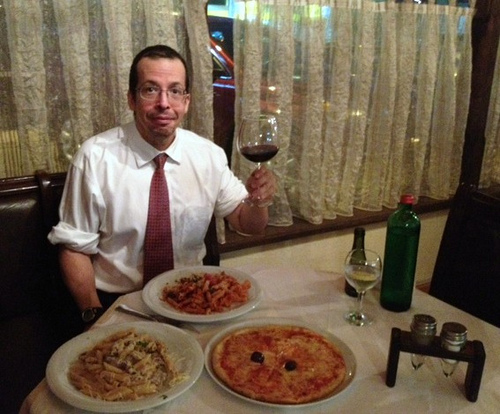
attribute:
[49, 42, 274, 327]
man — smiling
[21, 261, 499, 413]
table — white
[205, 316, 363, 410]
plate — white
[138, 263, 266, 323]
plate — white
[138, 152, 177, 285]
tie — red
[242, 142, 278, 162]
wine — red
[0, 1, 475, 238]
curtain — sheer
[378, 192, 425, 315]
bottle — green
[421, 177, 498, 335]
chair — brown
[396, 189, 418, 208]
cap — red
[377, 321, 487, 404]
holder — brown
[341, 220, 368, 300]
bottle — green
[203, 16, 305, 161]
car — red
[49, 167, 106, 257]
sleeve — rolled up